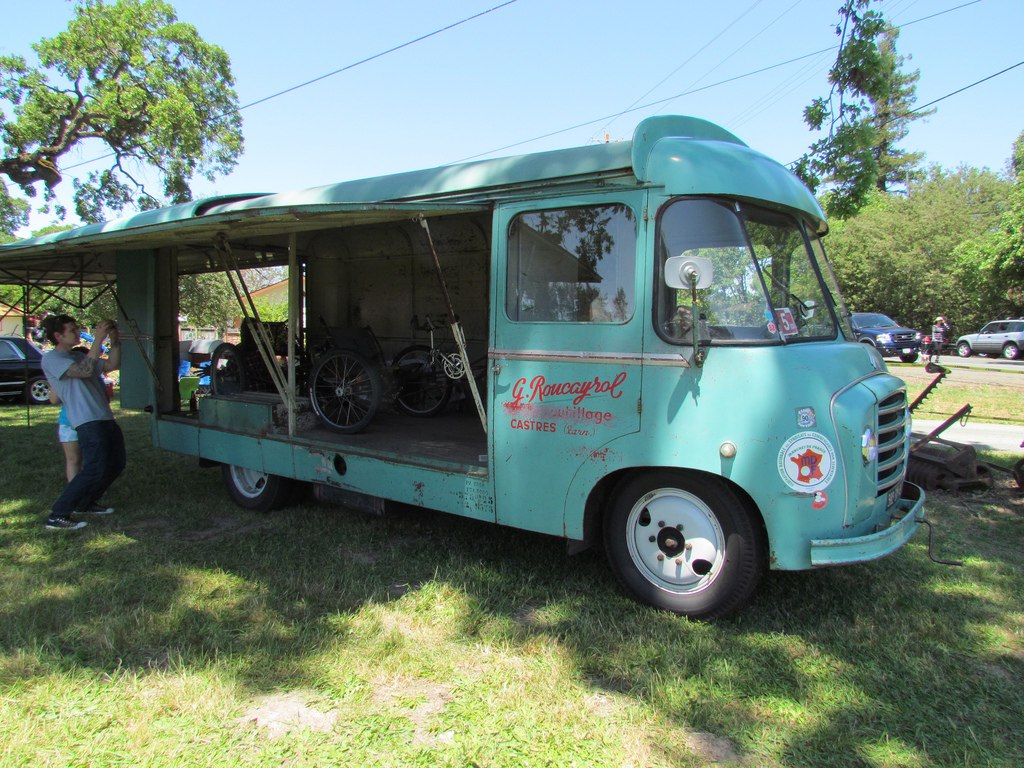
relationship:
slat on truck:
[875, 422, 911, 452] [0, 116, 927, 628]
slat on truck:
[875, 440, 907, 464] [0, 116, 927, 628]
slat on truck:
[868, 450, 910, 493] [0, 116, 927, 628]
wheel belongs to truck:
[220, 464, 288, 516] [0, 113, 966, 618]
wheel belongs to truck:
[599, 464, 767, 626] [0, 113, 966, 618]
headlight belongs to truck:
[860, 429, 877, 468] [0, 113, 966, 618]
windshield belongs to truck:
[654, 189, 855, 346] [0, 113, 966, 618]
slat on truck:
[874, 388, 910, 412] [0, 116, 927, 628]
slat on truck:
[869, 406, 909, 432] [0, 116, 927, 628]